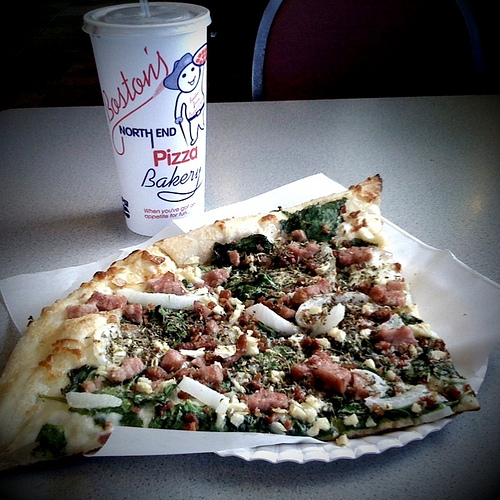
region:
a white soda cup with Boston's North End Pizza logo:
[76, 2, 217, 244]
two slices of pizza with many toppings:
[2, 191, 499, 467]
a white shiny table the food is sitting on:
[335, 104, 485, 181]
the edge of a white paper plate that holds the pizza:
[220, 441, 409, 480]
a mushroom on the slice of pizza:
[299, 296, 346, 330]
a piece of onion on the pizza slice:
[118, 284, 199, 315]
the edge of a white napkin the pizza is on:
[404, 220, 488, 290]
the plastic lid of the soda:
[80, 22, 222, 37]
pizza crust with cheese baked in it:
[99, 247, 162, 290]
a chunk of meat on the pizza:
[307, 349, 357, 395]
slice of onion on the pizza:
[126, 280, 207, 322]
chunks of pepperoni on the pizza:
[163, 339, 217, 376]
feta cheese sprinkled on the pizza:
[244, 329, 262, 361]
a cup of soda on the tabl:
[86, 9, 240, 248]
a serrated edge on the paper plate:
[273, 446, 348, 461]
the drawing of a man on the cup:
[166, 49, 211, 146]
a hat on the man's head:
[174, 52, 197, 70]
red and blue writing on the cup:
[123, 122, 195, 199]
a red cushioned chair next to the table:
[244, 0, 497, 97]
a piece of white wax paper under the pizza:
[7, 255, 65, 303]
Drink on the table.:
[57, 2, 292, 279]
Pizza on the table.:
[42, 231, 469, 495]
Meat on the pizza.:
[50, 277, 360, 448]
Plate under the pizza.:
[18, 236, 496, 481]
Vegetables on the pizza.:
[86, 270, 444, 465]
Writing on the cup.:
[103, 54, 212, 202]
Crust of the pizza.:
[90, 218, 280, 313]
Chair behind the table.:
[248, 19, 431, 191]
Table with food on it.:
[230, 72, 497, 369]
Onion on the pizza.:
[47, 373, 164, 425]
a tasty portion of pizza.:
[0, 191, 490, 448]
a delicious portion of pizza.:
[32, 213, 488, 474]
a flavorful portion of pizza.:
[5, 211, 480, 464]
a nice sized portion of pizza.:
[42, 187, 475, 472]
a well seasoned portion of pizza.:
[53, 188, 480, 467]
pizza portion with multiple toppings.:
[30, 208, 484, 465]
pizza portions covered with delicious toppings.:
[40, 205, 483, 459]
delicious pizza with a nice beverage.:
[32, 13, 482, 455]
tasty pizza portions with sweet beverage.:
[41, 8, 487, 450]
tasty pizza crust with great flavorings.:
[169, 175, 397, 250]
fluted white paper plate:
[235, 445, 427, 480]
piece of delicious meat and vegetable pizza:
[40, 163, 453, 485]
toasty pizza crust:
[41, 268, 127, 336]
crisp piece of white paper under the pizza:
[100, 416, 322, 458]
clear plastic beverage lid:
[82, 4, 229, 39]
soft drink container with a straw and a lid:
[94, 3, 226, 252]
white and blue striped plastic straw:
[139, 1, 156, 18]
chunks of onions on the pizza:
[251, 276, 348, 340]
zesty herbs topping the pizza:
[220, 262, 385, 369]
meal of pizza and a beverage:
[26, 0, 469, 495]